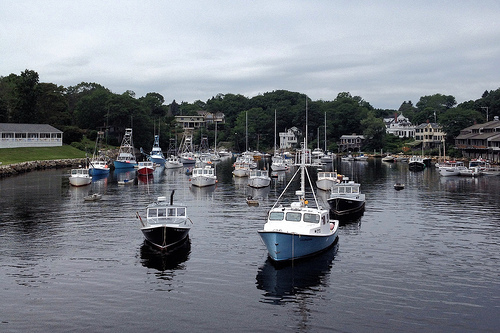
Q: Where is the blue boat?
A: In front of the black boat.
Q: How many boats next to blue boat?
A: One.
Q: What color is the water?
A: Gray.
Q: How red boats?
A: One.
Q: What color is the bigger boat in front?
A: Blue.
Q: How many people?
A: No people.